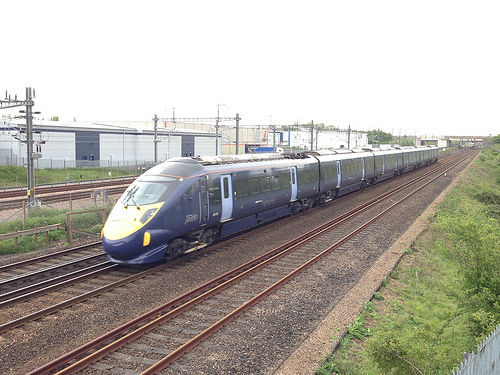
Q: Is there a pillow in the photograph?
A: No, there are no pillows.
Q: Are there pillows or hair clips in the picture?
A: No, there are no pillows or hair clips.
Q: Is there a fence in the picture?
A: Yes, there is a fence.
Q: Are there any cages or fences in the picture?
A: Yes, there is a fence.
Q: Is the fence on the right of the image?
A: Yes, the fence is on the right of the image.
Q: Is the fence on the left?
A: No, the fence is on the right of the image.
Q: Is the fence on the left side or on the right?
A: The fence is on the right of the image.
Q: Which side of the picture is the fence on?
A: The fence is on the right of the image.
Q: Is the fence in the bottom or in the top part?
A: The fence is in the bottom of the image.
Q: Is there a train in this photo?
A: Yes, there is a train.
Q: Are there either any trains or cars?
A: Yes, there is a train.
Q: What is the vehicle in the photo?
A: The vehicle is a train.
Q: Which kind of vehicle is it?
A: The vehicle is a train.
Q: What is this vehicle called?
A: This is a train.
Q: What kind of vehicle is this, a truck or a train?
A: This is a train.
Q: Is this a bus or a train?
A: This is a train.